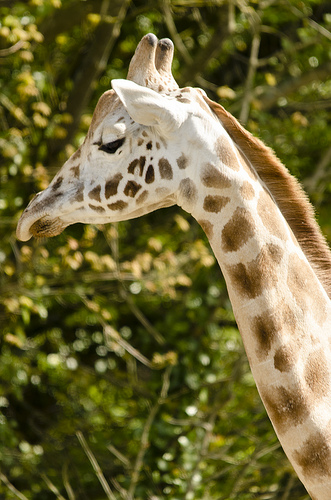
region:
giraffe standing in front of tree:
[3, 31, 328, 496]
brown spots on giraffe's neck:
[189, 142, 327, 497]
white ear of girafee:
[110, 77, 180, 126]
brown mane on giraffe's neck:
[217, 98, 329, 283]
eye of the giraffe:
[94, 122, 125, 155]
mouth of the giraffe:
[13, 195, 62, 246]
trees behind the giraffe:
[8, 6, 319, 489]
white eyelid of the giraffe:
[98, 124, 125, 141]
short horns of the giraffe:
[127, 28, 178, 88]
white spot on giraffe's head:
[181, 105, 218, 152]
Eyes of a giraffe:
[87, 121, 137, 164]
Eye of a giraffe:
[93, 117, 137, 166]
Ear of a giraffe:
[102, 73, 186, 136]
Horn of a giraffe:
[127, 21, 159, 84]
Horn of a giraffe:
[156, 28, 181, 80]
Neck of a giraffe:
[207, 97, 328, 421]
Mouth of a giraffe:
[17, 177, 67, 257]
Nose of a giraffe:
[17, 177, 46, 220]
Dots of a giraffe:
[108, 155, 179, 228]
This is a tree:
[61, 313, 189, 488]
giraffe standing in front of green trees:
[19, 31, 329, 493]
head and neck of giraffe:
[20, 39, 330, 487]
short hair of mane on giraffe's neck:
[212, 100, 328, 281]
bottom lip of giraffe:
[28, 219, 63, 244]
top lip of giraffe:
[10, 193, 49, 245]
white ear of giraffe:
[111, 78, 189, 126]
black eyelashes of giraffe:
[96, 137, 123, 152]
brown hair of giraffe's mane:
[210, 100, 328, 280]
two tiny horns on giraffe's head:
[127, 28, 179, 81]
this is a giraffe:
[10, 41, 324, 498]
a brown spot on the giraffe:
[274, 336, 300, 375]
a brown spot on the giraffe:
[259, 383, 306, 423]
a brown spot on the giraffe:
[201, 192, 231, 214]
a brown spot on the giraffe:
[259, 197, 282, 244]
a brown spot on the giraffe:
[104, 176, 119, 193]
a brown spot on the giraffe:
[171, 174, 197, 208]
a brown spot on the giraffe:
[49, 175, 63, 194]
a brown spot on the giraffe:
[145, 138, 152, 150]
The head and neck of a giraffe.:
[14, 33, 329, 499]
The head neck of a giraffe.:
[14, 31, 327, 496]